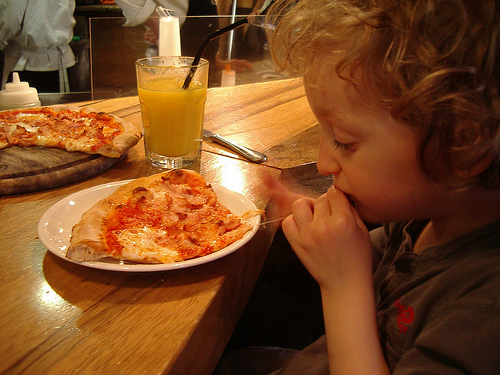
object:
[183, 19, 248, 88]
black straw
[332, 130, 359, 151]
eye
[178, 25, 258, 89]
straw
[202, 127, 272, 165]
spoon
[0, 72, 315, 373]
table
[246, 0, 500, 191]
hair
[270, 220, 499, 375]
brown shirt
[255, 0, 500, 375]
boy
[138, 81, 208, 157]
orange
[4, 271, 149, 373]
table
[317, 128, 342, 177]
nose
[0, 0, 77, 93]
person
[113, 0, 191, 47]
person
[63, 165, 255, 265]
cheese pizza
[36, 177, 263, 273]
plate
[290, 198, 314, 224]
finger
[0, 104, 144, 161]
pizza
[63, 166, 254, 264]
pizza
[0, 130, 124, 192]
tray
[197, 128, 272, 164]
butter knife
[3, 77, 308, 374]
counter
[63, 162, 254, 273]
kittens face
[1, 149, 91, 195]
board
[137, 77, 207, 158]
beverage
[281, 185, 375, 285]
hand